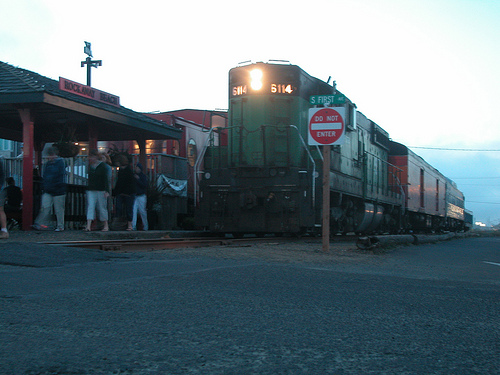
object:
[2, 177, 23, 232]
person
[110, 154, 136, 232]
person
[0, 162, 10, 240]
person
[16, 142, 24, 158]
person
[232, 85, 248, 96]
number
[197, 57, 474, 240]
train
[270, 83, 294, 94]
number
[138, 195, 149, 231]
leg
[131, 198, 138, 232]
leg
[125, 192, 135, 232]
leg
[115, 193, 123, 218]
leg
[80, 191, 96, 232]
leg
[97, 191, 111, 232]
leg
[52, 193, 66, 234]
leg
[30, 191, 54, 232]
leg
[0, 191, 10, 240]
leg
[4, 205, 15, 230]
leg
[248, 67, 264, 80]
light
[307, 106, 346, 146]
sign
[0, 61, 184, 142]
roof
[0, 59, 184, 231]
house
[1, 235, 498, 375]
road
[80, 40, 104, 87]
wind vale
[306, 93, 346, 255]
street sign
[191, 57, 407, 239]
car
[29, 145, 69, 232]
people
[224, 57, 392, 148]
top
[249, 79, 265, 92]
lights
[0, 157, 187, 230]
fence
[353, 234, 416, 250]
logs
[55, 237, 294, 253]
tracks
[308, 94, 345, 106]
sign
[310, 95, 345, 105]
s first st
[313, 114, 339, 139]
do not enter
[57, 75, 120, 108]
sign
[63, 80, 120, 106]
rockaway beach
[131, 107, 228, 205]
building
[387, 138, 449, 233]
car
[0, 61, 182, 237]
station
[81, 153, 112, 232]
person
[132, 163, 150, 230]
person